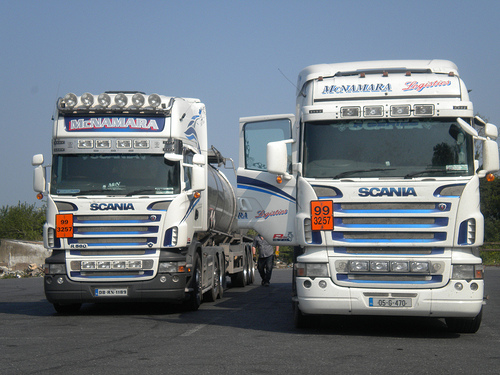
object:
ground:
[2, 322, 498, 371]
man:
[247, 222, 281, 284]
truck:
[239, 58, 500, 332]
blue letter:
[107, 202, 116, 209]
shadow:
[179, 282, 300, 333]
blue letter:
[405, 187, 415, 197]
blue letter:
[391, 187, 402, 195]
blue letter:
[379, 186, 389, 196]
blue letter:
[368, 186, 380, 197]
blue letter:
[357, 186, 369, 197]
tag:
[372, 296, 413, 309]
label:
[358, 185, 415, 198]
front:
[296, 178, 483, 310]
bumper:
[291, 255, 485, 317]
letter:
[125, 202, 135, 210]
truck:
[30, 89, 256, 320]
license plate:
[366, 295, 413, 307]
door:
[175, 150, 207, 249]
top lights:
[59, 91, 162, 109]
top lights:
[339, 103, 437, 119]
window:
[51, 154, 183, 195]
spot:
[396, 348, 404, 351]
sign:
[311, 198, 333, 228]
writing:
[401, 78, 451, 93]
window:
[302, 122, 472, 174]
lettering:
[357, 183, 417, 195]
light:
[342, 106, 362, 119]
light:
[364, 102, 385, 117]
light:
[391, 101, 411, 116]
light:
[414, 100, 434, 115]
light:
[64, 91, 78, 108]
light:
[82, 91, 93, 108]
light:
[97, 93, 110, 108]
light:
[129, 90, 145, 110]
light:
[147, 92, 162, 110]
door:
[237, 111, 301, 245]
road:
[10, 320, 498, 366]